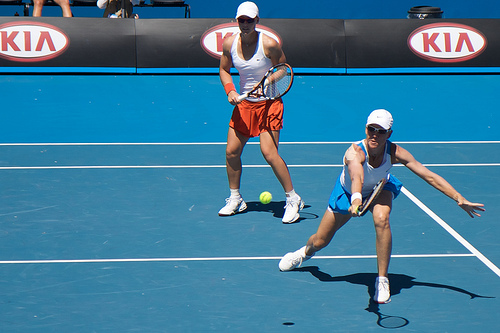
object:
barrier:
[1, 17, 500, 73]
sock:
[284, 189, 299, 200]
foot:
[280, 194, 305, 224]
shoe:
[282, 196, 307, 224]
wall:
[0, 16, 76, 69]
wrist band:
[351, 192, 363, 205]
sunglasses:
[237, 17, 257, 23]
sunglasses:
[367, 124, 390, 133]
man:
[214, 0, 308, 225]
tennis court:
[0, 68, 500, 333]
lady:
[211, 1, 303, 223]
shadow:
[243, 200, 311, 220]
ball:
[260, 191, 272, 204]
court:
[0, 73, 499, 330]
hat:
[233, 0, 259, 22]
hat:
[363, 106, 393, 131]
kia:
[419, 29, 477, 55]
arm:
[218, 36, 236, 96]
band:
[223, 82, 237, 95]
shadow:
[296, 264, 498, 332]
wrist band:
[223, 82, 237, 95]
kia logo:
[1, 20, 70, 62]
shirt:
[229, 31, 279, 102]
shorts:
[229, 100, 289, 139]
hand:
[458, 196, 486, 219]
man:
[278, 109, 488, 304]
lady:
[273, 107, 484, 308]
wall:
[404, 14, 500, 76]